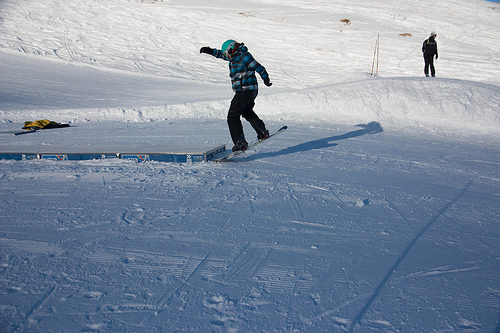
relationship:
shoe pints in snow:
[230, 139, 248, 154] [0, 0, 500, 333]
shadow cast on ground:
[221, 119, 383, 165] [12, 117, 497, 331]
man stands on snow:
[422, 33, 438, 78] [0, 158, 500, 331]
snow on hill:
[270, 80, 497, 137] [301, 80, 498, 134]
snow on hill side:
[0, 0, 500, 333] [1, 0, 497, 148]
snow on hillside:
[0, 0, 500, 333] [2, 2, 497, 327]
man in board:
[199, 40, 270, 151] [226, 126, 287, 160]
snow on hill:
[0, 0, 500, 333] [2, 6, 499, 133]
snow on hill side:
[0, 0, 500, 333] [9, 2, 498, 92]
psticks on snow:
[374, 34, 381, 74] [0, 0, 500, 333]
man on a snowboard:
[199, 40, 270, 151] [210, 125, 290, 167]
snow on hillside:
[0, 0, 500, 333] [0, 2, 498, 78]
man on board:
[199, 40, 270, 151] [210, 120, 290, 180]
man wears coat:
[199, 40, 270, 151] [204, 22, 285, 98]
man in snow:
[199, 40, 270, 151] [0, 0, 500, 333]